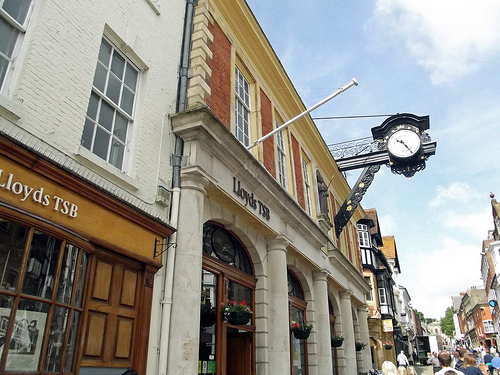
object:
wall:
[2, 1, 179, 217]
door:
[80, 248, 145, 371]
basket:
[229, 302, 255, 327]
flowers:
[230, 300, 251, 309]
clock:
[367, 112, 437, 178]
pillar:
[170, 175, 209, 373]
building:
[187, 0, 372, 374]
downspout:
[158, 0, 200, 374]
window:
[77, 21, 149, 179]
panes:
[81, 97, 141, 157]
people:
[471, 340, 497, 373]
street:
[424, 368, 432, 372]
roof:
[366, 207, 379, 233]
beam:
[335, 151, 388, 171]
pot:
[224, 315, 256, 325]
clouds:
[388, 1, 484, 86]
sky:
[283, 17, 367, 68]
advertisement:
[3, 306, 42, 371]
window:
[3, 210, 91, 373]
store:
[2, 146, 156, 373]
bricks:
[35, 74, 56, 80]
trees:
[434, 311, 456, 338]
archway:
[204, 201, 271, 264]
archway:
[283, 252, 318, 312]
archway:
[324, 285, 342, 313]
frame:
[5, 206, 107, 252]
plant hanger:
[227, 309, 252, 327]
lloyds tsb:
[231, 177, 274, 222]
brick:
[38, 114, 49, 123]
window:
[231, 59, 303, 161]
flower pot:
[296, 322, 312, 339]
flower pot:
[332, 334, 344, 346]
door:
[224, 333, 251, 373]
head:
[438, 353, 453, 365]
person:
[435, 351, 463, 373]